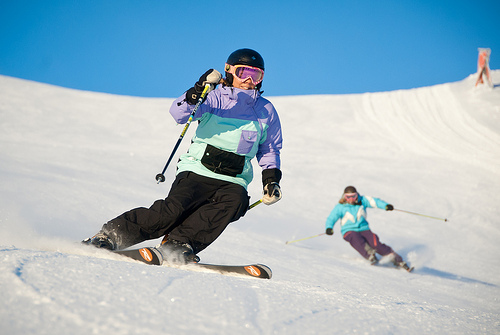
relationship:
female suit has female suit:
[73, 42, 303, 273] [92, 46, 286, 270]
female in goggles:
[82, 45, 283, 262] [223, 62, 266, 84]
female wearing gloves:
[82, 45, 283, 262] [259, 167, 285, 204]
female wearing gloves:
[82, 45, 283, 262] [185, 67, 222, 105]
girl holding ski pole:
[324, 184, 416, 273] [391, 206, 450, 222]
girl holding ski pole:
[324, 184, 416, 273] [284, 227, 327, 245]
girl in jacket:
[324, 184, 416, 273] [321, 197, 389, 230]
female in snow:
[82, 45, 283, 262] [81, 271, 482, 330]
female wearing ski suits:
[82, 48, 285, 268] [100, 83, 393, 258]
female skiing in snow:
[82, 48, 285, 268] [5, 64, 491, 330]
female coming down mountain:
[82, 48, 285, 268] [0, 65, 498, 333]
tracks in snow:
[10, 237, 352, 332] [5, 64, 491, 330]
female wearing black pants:
[82, 48, 285, 268] [97, 171, 249, 258]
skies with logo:
[179, 261, 274, 280] [241, 260, 261, 280]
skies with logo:
[108, 244, 165, 275] [136, 244, 154, 265]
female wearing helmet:
[82, 48, 285, 268] [225, 48, 269, 89]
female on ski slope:
[82, 48, 285, 268] [67, 234, 290, 326]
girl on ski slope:
[324, 184, 416, 273] [4, 61, 485, 328]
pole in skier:
[148, 78, 217, 188] [66, 39, 315, 293]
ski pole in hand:
[249, 195, 263, 212] [260, 177, 280, 202]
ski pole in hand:
[284, 230, 329, 246] [323, 227, 334, 237]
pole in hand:
[158, 78, 214, 180] [187, 70, 220, 100]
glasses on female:
[224, 64, 262, 86] [82, 48, 285, 268]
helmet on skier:
[215, 42, 276, 83] [168, 32, 290, 201]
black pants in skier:
[97, 171, 249, 258] [102, 29, 287, 263]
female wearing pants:
[82, 48, 285, 268] [340, 230, 422, 270]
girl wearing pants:
[324, 186, 410, 270] [343, 231, 401, 265]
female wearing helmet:
[82, 48, 285, 268] [226, 47, 264, 89]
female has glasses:
[82, 48, 285, 268] [230, 66, 262, 83]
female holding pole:
[82, 48, 285, 268] [153, 78, 213, 183]